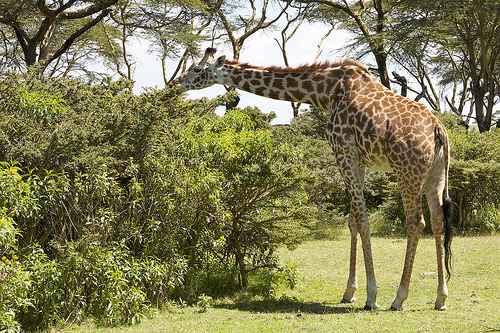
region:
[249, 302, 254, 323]
part of a shadow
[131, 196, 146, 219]
part of a bush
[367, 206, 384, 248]
leg of a giraffe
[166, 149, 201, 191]
part of a tree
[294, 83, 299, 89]
neck of a giraffe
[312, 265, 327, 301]
part of a lawn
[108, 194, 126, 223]
part of a bush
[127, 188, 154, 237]
part of a forest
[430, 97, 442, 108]
part of a tree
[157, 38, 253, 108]
A giraffe grazing on a bush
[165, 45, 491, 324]
A giraffe in an open green field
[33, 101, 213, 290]
Lush green bushes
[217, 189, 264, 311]
Branches on a bush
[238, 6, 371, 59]
A clear blue sky in the midst of trees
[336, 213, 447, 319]
A giraffe's four legs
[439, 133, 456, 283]
A giraffe's black tail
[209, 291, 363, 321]
Shadow cast from the sun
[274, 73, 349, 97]
Brown and white markings on a giraffe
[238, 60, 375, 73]
The brown hair on the giraffe's neck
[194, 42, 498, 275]
tall giraffe eating leaves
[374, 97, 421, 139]
brown and yellow spots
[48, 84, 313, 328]
thick green bushes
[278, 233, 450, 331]
short green grass on ground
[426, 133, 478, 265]
black tail hanging from giraffe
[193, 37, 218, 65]
small horns on giraffe's head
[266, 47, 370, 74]
brown mane on giraffe's neck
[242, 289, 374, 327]
shadow of animal on grass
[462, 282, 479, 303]
small leaves on grass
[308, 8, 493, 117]
tall trees in background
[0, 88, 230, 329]
a leafy green bush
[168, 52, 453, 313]
a giraffe eating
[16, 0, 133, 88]
a brown tree trunk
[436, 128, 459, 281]
tail of a giraffe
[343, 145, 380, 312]
front leg of a giraffe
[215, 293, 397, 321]
a shadow on the ground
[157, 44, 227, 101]
a giraffes head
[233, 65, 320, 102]
a giraffe neck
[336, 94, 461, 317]
the legs of a giraffe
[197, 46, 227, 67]
horns of a giraffe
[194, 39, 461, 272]
TALL GIRAFFE EATING LEAVES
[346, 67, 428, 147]
BROWN AND YELLOW SPOTS ON GIRAFFE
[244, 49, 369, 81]
BROWN MANE ON GIRAFFE'S NECK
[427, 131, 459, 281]
BLACK TAIL ON GIRAFFE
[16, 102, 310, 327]
THICK GREEN BUSH ON LEFT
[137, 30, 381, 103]
WHITE AND BLUE SKY IN BACKGROUND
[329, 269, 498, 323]
WHITE HOOFS OF GIRAFFE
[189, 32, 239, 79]
HORNS ON GIRAFFE'S HEAD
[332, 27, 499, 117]
TALL TREES IN BACKGROUND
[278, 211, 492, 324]
SHORT GRASS UNDER GIRAFFE